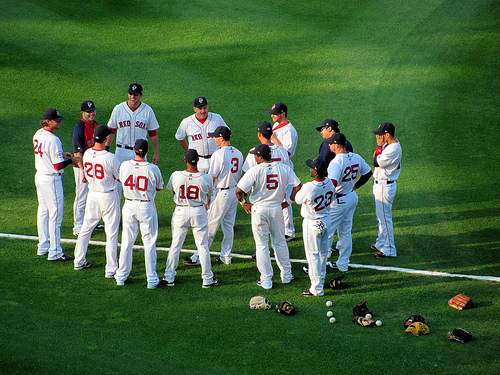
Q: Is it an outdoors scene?
A: Yes, it is outdoors.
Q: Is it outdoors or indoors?
A: It is outdoors.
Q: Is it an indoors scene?
A: No, it is outdoors.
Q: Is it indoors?
A: No, it is outdoors.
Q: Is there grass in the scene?
A: Yes, there is grass.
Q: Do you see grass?
A: Yes, there is grass.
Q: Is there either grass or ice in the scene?
A: Yes, there is grass.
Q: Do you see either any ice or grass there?
A: Yes, there is grass.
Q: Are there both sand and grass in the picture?
A: No, there is grass but no sand.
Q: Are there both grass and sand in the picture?
A: No, there is grass but no sand.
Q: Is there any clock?
A: No, there are no clocks.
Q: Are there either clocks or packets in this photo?
A: No, there are no clocks or packets.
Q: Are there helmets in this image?
A: No, there are no helmets.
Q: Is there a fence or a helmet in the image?
A: No, there are no helmets or fences.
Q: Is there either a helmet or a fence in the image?
A: No, there are no helmets or fences.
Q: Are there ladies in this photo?
A: No, there are no ladies.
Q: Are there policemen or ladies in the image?
A: No, there are no ladies or policemen.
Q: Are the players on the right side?
A: Yes, the players are on the right of the image.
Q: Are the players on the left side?
A: No, the players are on the right of the image.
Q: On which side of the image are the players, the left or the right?
A: The players are on the right of the image.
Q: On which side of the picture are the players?
A: The players are on the right of the image.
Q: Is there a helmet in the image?
A: No, there are no helmets.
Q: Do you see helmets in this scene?
A: No, there are no helmets.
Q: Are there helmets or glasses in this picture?
A: No, there are no helmets or glasses.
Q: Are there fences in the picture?
A: No, there are no fences.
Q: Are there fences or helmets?
A: No, there are no fences or helmets.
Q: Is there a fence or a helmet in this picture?
A: No, there are no fences or helmets.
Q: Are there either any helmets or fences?
A: No, there are no fences or helmets.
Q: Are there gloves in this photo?
A: Yes, there are gloves.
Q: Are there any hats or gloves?
A: Yes, there are gloves.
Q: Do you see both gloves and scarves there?
A: No, there are gloves but no scarves.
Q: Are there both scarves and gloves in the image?
A: No, there are gloves but no scarves.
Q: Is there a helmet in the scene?
A: No, there are no helmets.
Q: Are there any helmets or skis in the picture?
A: No, there are no helmets or skis.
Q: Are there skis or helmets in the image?
A: No, there are no helmets or skis.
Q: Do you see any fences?
A: No, there are no fences.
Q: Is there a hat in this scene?
A: Yes, there is a hat.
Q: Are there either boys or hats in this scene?
A: Yes, there is a hat.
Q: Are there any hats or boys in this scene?
A: Yes, there is a hat.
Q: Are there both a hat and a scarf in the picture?
A: No, there is a hat but no scarves.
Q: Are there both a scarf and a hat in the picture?
A: No, there is a hat but no scarves.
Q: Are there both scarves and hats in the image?
A: No, there is a hat but no scarves.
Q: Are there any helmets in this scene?
A: No, there are no helmets.